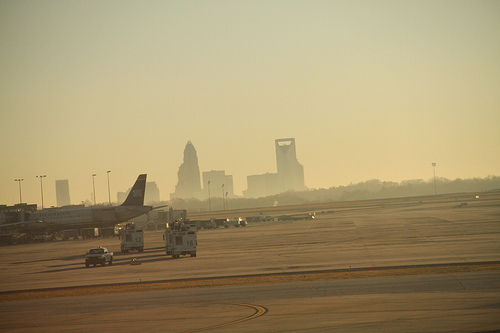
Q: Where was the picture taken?
A: Airport.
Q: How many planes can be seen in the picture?
A: 1.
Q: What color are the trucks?
A: White.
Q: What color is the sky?
A: Yellow.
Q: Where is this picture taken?
A: An airport.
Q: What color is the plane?
A: White.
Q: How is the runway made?
A: Of concrete.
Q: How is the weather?
A: Overcast.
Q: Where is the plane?
A: On the runway.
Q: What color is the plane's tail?
A: Red.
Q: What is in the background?
A: A city.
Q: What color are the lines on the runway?
A: Yellow.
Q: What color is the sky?
A: Gray.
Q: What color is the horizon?
A: Brown.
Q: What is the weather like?
A: Hazy.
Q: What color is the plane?
A: White.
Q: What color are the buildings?
A: Silver.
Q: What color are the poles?
A: Gray.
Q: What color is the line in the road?
A: Yellow.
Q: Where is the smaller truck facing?
A: Toward the camera.